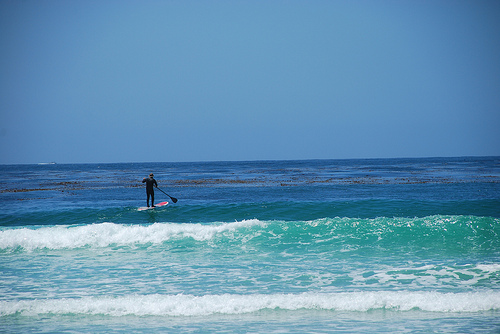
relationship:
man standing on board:
[141, 173, 157, 208] [139, 198, 172, 218]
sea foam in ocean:
[3, 216, 267, 259] [2, 156, 498, 333]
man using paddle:
[141, 173, 157, 208] [152, 184, 181, 205]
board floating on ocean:
[139, 198, 172, 218] [2, 156, 498, 333]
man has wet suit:
[141, 173, 157, 208] [142, 176, 160, 209]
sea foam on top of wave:
[3, 216, 267, 259] [2, 207, 499, 315]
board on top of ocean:
[139, 198, 172, 218] [2, 156, 498, 333]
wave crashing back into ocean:
[2, 207, 499, 315] [2, 156, 498, 333]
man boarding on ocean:
[141, 173, 157, 208] [2, 156, 498, 333]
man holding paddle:
[141, 173, 157, 208] [152, 184, 181, 205]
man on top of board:
[141, 173, 157, 208] [139, 198, 172, 218]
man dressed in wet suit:
[141, 173, 157, 208] [142, 176, 160, 209]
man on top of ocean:
[141, 173, 157, 208] [2, 156, 498, 333]